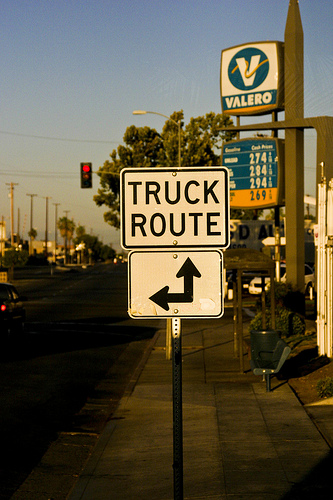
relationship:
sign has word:
[216, 44, 281, 115] [222, 92, 277, 111]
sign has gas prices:
[223, 137, 281, 209] [247, 139, 276, 205]